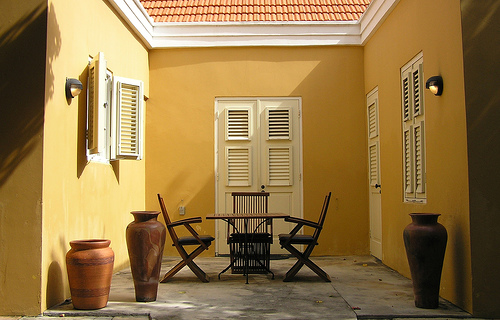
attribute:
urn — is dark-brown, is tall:
[399, 207, 454, 311]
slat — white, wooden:
[268, 113, 292, 120]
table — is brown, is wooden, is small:
[207, 202, 289, 288]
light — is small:
[62, 79, 79, 97]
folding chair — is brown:
[157, 192, 222, 282]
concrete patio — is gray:
[43, 254, 475, 319]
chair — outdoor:
[277, 192, 334, 282]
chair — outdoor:
[155, 192, 217, 284]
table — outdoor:
[210, 210, 291, 278]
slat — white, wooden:
[122, 116, 135, 121]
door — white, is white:
[214, 96, 306, 253]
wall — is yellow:
[150, 47, 368, 253]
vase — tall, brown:
[402, 210, 446, 309]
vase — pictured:
[124, 209, 166, 301]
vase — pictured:
[64, 238, 115, 310]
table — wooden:
[206, 213, 287, 285]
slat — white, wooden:
[120, 92, 135, 98]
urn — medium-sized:
[56, 222, 119, 317]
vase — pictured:
[403, 205, 449, 310]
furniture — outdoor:
[72, 156, 401, 318]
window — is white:
[82, 57, 113, 165]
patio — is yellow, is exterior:
[79, 53, 459, 319]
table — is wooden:
[212, 208, 289, 287]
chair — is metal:
[225, 189, 275, 273]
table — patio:
[205, 210, 290, 275]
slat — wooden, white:
[121, 135, 140, 141]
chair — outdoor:
[283, 189, 335, 266]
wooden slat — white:
[122, 92, 134, 152]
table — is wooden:
[204, 206, 292, 284]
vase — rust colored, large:
[51, 224, 122, 316]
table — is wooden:
[203, 202, 303, 285]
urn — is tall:
[122, 207, 178, 305]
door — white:
[350, 77, 390, 268]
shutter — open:
[107, 65, 147, 164]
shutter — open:
[80, 44, 112, 164]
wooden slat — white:
[228, 116, 250, 120]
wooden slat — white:
[268, 116, 294, 125]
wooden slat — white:
[121, 94, 142, 102]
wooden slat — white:
[118, 101, 143, 111]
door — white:
[208, 94, 303, 256]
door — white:
[364, 85, 384, 263]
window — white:
[401, 50, 425, 200]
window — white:
[84, 62, 114, 162]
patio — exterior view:
[55, 0, 478, 317]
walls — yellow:
[38, 0, 470, 317]